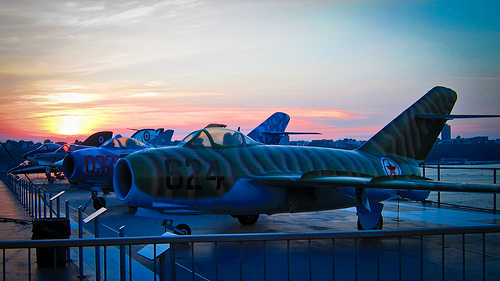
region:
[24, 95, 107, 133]
Setting sun on the horizon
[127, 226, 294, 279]
A metal fence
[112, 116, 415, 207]
An old military jet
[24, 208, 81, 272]
A dark colored garbage can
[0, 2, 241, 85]
Clouds in the sky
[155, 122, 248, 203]
The number "624" on the side of a jet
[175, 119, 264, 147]
The cockpit of an old jet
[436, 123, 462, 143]
A building in the distance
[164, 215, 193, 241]
The front wheel of a jet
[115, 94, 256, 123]
Pink tinted clouds at dusk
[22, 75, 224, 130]
yellow and orange sunset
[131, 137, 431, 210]
green striped plane number 624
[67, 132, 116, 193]
striped plane number 033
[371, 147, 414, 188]
red star emblem on front plane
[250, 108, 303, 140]
striped tail of second plane in row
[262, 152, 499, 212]
wing of green striped plane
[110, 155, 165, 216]
nose of green striped plane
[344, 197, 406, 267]
rear landing gear of green striped plane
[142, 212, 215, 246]
front landing gear of green plane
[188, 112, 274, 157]
cockpit of green plane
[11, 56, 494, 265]
vintage military planes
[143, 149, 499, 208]
camouflage airbrushed detail on plane body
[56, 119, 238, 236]
planes have identification numbers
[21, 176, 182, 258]
signs for each plane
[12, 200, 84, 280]
trash can for visitors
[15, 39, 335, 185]
sun is setting in the back ground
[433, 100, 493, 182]
city in the distance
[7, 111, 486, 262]
railing shows planes don't fly currently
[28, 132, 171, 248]
various paint colors and patterns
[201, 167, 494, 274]
planes parked on concrete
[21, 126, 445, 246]
There are 4 planes here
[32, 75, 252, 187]
The sun is setting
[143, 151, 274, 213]
This plane has 624 on it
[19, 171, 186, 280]
The planes are behind a fence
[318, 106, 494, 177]
There are buildings in the back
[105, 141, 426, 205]
This plane has a red star on it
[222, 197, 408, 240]
The plane's wheels are down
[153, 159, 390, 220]
The plane is paited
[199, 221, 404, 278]
The pavement looks wet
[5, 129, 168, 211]
There are trees in the back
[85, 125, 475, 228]
airplanes sunset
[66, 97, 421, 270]
airplanes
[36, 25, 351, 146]
the sun is setting for the day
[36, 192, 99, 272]
fence around the airplanes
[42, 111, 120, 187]
another airplane in the background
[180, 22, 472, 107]
the sky is looking dark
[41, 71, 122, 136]
the sun is setting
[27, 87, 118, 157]
sunset in the background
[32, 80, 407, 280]
airplanes in an airport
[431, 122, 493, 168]
buildings in the background